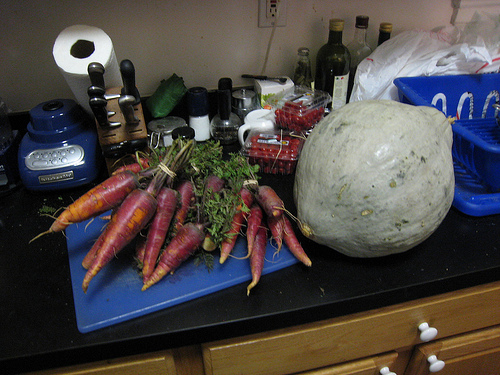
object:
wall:
[0, 0, 500, 119]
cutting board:
[63, 186, 303, 335]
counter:
[0, 78, 500, 375]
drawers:
[23, 349, 184, 374]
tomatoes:
[260, 150, 271, 156]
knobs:
[378, 364, 399, 374]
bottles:
[344, 12, 375, 94]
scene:
[0, 0, 500, 375]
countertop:
[0, 82, 500, 375]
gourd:
[289, 97, 461, 261]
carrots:
[138, 220, 207, 294]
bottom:
[14, 131, 103, 194]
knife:
[87, 96, 123, 130]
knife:
[117, 94, 140, 125]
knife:
[119, 58, 142, 107]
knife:
[87, 61, 106, 91]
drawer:
[199, 280, 500, 375]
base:
[15, 96, 102, 192]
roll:
[50, 23, 124, 119]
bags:
[347, 25, 466, 103]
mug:
[237, 107, 279, 148]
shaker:
[187, 86, 212, 144]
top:
[185, 86, 210, 117]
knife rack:
[94, 96, 148, 147]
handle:
[88, 95, 111, 126]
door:
[27, 346, 181, 374]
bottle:
[312, 16, 353, 111]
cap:
[328, 17, 345, 32]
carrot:
[78, 187, 160, 293]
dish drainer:
[391, 71, 500, 219]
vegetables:
[165, 179, 195, 238]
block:
[92, 82, 150, 178]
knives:
[87, 84, 117, 118]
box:
[264, 81, 333, 134]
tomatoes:
[292, 118, 297, 121]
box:
[240, 127, 306, 176]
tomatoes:
[285, 149, 291, 153]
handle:
[424, 353, 447, 374]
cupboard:
[21, 278, 500, 375]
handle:
[417, 321, 439, 343]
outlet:
[256, 0, 288, 29]